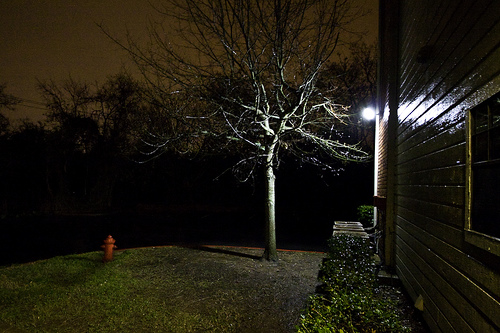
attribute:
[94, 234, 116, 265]
hydrant — fire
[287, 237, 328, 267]
line — red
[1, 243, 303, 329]
grass — area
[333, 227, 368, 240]
unit — air conditioner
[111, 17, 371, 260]
tree — bare